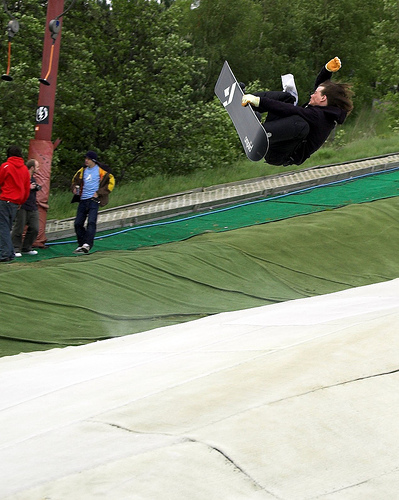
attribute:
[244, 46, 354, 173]
man — doing trick, snowboarding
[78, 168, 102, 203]
shirt — blue, light blue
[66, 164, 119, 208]
jacket — yellow, brown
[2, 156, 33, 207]
jacket — hoodie, red, bright red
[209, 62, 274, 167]
snowboard — black, white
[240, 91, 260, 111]
glove — white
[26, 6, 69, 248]
pole — rusty, large, brown, red, deep red, burgundy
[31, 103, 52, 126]
sticker — white, lightening symbol, black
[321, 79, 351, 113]
hair — brown, dark, long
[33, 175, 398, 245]
hose — blue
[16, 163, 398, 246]
mats — green, side area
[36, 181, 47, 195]
camera — black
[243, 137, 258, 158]
letters — white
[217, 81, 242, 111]
design — white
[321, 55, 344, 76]
glove — yellow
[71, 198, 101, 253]
jeans — blue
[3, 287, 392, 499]
ground — skateboarding, white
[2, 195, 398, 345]
mats — green, cushioning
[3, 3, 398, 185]
trees — grouped, healthy, green, dark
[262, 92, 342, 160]
shirt — black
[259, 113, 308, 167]
pants — black, dark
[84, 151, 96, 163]
hat — black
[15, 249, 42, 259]
shoes — white